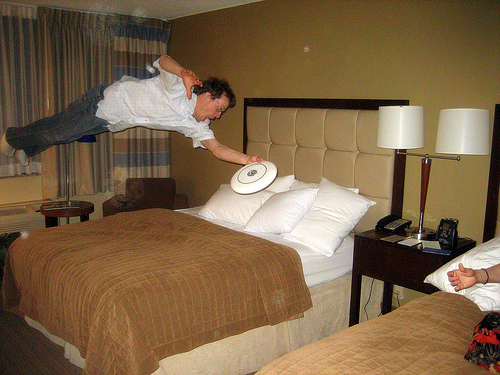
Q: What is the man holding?
A: A frisbee.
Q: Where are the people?
A: In a hotel room.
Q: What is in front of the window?
A: Curtain.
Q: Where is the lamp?
A: The table.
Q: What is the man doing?
A: Jumping.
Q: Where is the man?
A: In the air.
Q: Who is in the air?
A: A man.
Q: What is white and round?
A: Frisbee.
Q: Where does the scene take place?
A: In a hotel room.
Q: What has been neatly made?
A: The left bed.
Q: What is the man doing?
A: Playing frisbee.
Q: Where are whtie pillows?
A: On the beds.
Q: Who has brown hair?
A: The man.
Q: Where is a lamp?
A: On end table.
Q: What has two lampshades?
A: The lamp.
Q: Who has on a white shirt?
A: Man in the air.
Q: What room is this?
A: A bedroom.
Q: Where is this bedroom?
A: A hotel.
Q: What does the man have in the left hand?
A: A frisbee.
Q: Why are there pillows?
A: To rest the head of the people.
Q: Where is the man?
A: In the middle of the air.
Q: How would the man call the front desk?
A: With the telephone between beds.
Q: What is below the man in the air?
A: A bed.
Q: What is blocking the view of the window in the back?
A: Curtains.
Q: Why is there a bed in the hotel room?
A: To rest.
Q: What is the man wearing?
A: White long sleeved shirt.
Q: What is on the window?
A: Brown beige and blue curtains.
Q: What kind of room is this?
A: Bedroom.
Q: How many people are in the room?
A: Two.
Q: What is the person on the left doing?
A: Catching a frisbee.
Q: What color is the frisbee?
A: White.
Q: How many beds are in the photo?
A: Two.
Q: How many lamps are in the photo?
A: One.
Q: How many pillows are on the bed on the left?
A: Five.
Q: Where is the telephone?
A: Night stand.